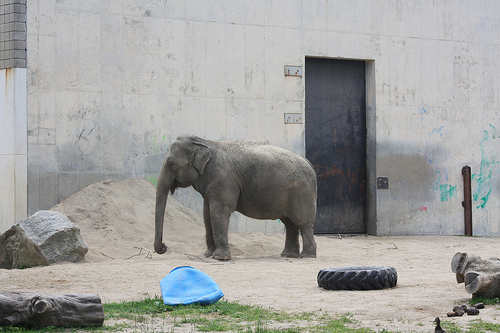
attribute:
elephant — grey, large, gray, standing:
[153, 135, 320, 261]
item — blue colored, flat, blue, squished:
[159, 266, 224, 308]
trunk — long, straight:
[154, 167, 174, 255]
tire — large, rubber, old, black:
[317, 265, 400, 289]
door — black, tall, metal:
[306, 56, 368, 236]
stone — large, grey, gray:
[0, 210, 91, 269]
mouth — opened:
[172, 178, 184, 188]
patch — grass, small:
[0, 294, 375, 333]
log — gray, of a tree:
[0, 290, 107, 328]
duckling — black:
[432, 316, 445, 333]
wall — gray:
[0, 0, 500, 238]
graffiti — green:
[436, 124, 497, 211]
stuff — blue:
[414, 105, 449, 181]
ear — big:
[191, 142, 214, 174]